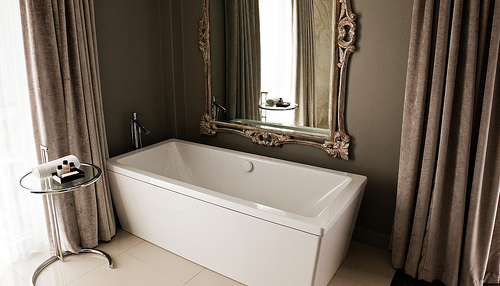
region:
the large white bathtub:
[105, 135, 367, 283]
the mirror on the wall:
[197, 2, 355, 159]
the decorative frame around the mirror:
[197, 0, 357, 160]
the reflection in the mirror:
[210, 0, 331, 138]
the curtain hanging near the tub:
[391, 0, 497, 284]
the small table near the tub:
[19, 144, 114, 284]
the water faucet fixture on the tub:
[127, 109, 147, 149]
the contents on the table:
[32, 142, 86, 186]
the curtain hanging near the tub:
[16, 0, 118, 255]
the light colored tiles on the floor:
[0, 226, 395, 283]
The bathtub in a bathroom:
[91, 121, 390, 284]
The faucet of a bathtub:
[121, 99, 163, 163]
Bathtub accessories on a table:
[21, 128, 124, 283]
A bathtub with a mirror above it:
[97, 2, 379, 283]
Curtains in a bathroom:
[15, 0, 135, 267]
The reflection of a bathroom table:
[238, 71, 306, 147]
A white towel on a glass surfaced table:
[33, 149, 83, 179]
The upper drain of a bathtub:
[231, 157, 264, 179]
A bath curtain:
[381, 0, 498, 284]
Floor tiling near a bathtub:
[118, 233, 221, 284]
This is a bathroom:
[5, 1, 498, 283]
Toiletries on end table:
[35, 147, 87, 194]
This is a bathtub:
[99, 122, 391, 284]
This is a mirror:
[194, 0, 371, 145]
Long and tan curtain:
[400, 3, 498, 285]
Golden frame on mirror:
[199, 2, 358, 157]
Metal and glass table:
[16, 143, 121, 282]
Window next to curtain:
[2, 0, 54, 257]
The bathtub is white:
[92, 116, 374, 284]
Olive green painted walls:
[92, 1, 440, 283]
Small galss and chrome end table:
[17, 138, 114, 285]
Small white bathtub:
[97, 82, 378, 285]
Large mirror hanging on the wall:
[185, 2, 379, 164]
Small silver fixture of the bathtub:
[113, 106, 157, 150]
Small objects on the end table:
[40, 158, 89, 186]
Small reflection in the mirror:
[243, 82, 301, 127]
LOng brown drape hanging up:
[386, 3, 495, 283]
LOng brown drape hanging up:
[12, 3, 102, 258]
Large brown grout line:
[119, 234, 191, 283]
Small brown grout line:
[337, 268, 358, 285]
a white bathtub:
[107, 133, 367, 283]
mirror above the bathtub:
[200, 7, 354, 154]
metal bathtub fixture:
[130, 110, 148, 147]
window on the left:
[5, 5, 59, 260]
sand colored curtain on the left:
[22, 3, 113, 257]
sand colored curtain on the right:
[395, 3, 497, 285]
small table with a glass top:
[25, 159, 114, 282]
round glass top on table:
[27, 159, 97, 194]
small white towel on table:
[37, 154, 76, 177]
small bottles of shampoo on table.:
[56, 160, 75, 173]